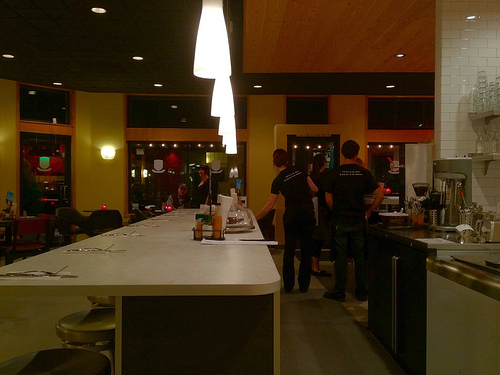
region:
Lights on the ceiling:
[1, 1, 409, 94]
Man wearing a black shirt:
[321, 134, 383, 232]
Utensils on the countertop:
[1, 261, 75, 284]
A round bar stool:
[52, 303, 122, 354]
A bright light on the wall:
[94, 134, 120, 171]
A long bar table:
[0, 205, 286, 372]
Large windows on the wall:
[11, 81, 341, 227]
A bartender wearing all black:
[258, 149, 322, 295]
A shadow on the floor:
[290, 291, 367, 373]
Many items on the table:
[189, 186, 257, 244]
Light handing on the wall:
[92, 133, 119, 178]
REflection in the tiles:
[458, 8, 483, 48]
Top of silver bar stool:
[2, 344, 87, 374]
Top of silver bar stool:
[50, 307, 117, 344]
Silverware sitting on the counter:
[5, 263, 80, 286]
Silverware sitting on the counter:
[57, 233, 130, 268]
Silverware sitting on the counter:
[97, 226, 141, 243]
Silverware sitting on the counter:
[118, 220, 156, 234]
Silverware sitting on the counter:
[143, 213, 173, 227]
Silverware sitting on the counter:
[0, 217, 139, 294]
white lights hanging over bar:
[186, 2, 248, 155]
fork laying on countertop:
[6, 263, 82, 289]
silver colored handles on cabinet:
[387, 253, 411, 363]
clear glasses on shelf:
[470, 68, 498, 121]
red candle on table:
[82, 200, 124, 218]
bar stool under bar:
[40, 300, 138, 365]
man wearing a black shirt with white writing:
[319, 139, 389, 306]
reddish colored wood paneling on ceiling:
[241, 0, 442, 77]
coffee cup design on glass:
[35, 154, 57, 175]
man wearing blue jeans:
[320, 133, 390, 315]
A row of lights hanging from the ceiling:
[186, 7, 250, 157]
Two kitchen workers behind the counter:
[265, 128, 390, 312]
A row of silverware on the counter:
[4, 215, 183, 290]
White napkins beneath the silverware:
[7, 266, 69, 287]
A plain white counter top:
[107, 245, 289, 299]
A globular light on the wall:
[92, 143, 123, 165]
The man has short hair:
[337, 138, 364, 162]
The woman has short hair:
[267, 146, 289, 166]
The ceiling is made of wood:
[257, 8, 376, 65]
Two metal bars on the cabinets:
[382, 252, 410, 352]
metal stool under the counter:
[55, 305, 117, 349]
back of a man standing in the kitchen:
[320, 139, 381, 305]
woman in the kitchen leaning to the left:
[250, 148, 317, 294]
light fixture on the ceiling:
[196, 0, 237, 156]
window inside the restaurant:
[130, 140, 246, 213]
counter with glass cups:
[470, 65, 498, 123]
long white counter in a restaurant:
[0, 203, 280, 293]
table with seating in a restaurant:
[0, 213, 72, 257]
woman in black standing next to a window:
[194, 164, 214, 205]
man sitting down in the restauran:
[167, 183, 189, 210]